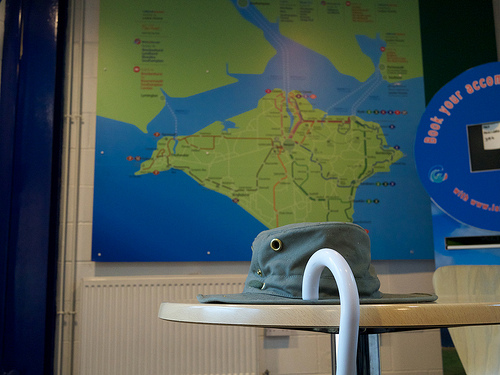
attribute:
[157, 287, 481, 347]
table — round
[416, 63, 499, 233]
advertising — circle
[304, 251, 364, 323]
pole — metal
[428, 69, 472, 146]
writing — red 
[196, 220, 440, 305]
hat — blue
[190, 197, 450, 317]
hat — grey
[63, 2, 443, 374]
wall — white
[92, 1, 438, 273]
map — blue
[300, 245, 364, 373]
hook — white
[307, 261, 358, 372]
object — white